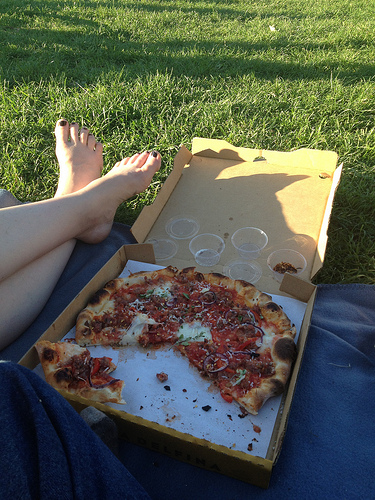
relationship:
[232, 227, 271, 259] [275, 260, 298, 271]
container with seasoning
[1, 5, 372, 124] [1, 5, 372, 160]
grass in grass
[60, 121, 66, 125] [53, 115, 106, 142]
nail polish on toenails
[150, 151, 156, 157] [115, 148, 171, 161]
nail polish on toenails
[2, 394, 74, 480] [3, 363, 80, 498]
denim worn person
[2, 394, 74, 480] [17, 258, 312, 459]
denim touching box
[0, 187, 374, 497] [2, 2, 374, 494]
blanket on ground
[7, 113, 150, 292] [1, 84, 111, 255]
leg of a female